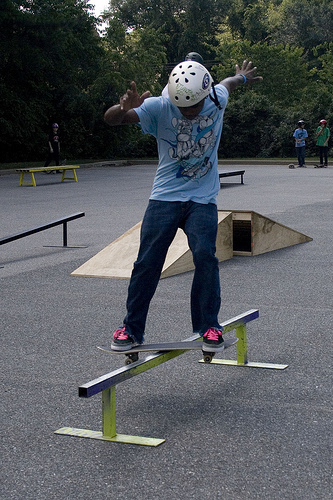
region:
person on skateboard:
[97, 71, 248, 363]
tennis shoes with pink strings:
[112, 321, 225, 352]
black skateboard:
[94, 335, 234, 362]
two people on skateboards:
[290, 114, 330, 169]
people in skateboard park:
[286, 117, 331, 169]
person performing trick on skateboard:
[95, 58, 267, 361]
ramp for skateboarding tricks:
[65, 197, 235, 276]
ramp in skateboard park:
[232, 205, 312, 253]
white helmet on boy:
[150, 58, 222, 112]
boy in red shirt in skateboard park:
[317, 116, 331, 162]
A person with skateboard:
[92, 80, 241, 358]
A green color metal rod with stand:
[69, 375, 169, 459]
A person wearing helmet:
[161, 54, 227, 109]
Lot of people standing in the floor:
[49, 119, 331, 152]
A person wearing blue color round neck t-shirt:
[155, 103, 231, 199]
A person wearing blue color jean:
[129, 205, 225, 322]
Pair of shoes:
[108, 329, 238, 347]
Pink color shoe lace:
[111, 326, 127, 338]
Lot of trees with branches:
[54, 3, 300, 51]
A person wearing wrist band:
[236, 70, 249, 86]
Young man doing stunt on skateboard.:
[92, 59, 273, 355]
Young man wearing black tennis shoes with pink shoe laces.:
[197, 326, 228, 353]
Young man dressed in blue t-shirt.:
[133, 82, 233, 204]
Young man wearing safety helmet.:
[167, 60, 215, 107]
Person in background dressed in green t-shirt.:
[314, 126, 332, 148]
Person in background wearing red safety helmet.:
[318, 119, 328, 126]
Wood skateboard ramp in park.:
[71, 207, 317, 280]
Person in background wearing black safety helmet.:
[295, 116, 307, 128]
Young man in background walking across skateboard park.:
[39, 117, 67, 173]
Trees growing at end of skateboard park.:
[5, 10, 106, 156]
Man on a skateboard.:
[102, 58, 262, 352]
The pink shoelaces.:
[203, 329, 221, 341]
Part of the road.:
[22, 289, 76, 357]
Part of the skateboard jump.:
[237, 208, 312, 255]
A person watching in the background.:
[43, 122, 63, 173]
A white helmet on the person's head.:
[166, 61, 220, 110]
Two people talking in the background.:
[292, 116, 329, 168]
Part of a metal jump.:
[55, 370, 172, 450]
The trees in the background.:
[239, 102, 283, 151]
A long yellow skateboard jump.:
[15, 165, 81, 184]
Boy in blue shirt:
[96, 47, 279, 302]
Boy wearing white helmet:
[91, 40, 270, 222]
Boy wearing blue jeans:
[98, 48, 277, 365]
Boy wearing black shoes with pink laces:
[89, 50, 268, 362]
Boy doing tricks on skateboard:
[84, 46, 291, 494]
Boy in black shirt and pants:
[33, 112, 82, 174]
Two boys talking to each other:
[277, 106, 332, 160]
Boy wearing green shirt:
[311, 112, 332, 167]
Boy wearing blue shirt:
[283, 111, 311, 170]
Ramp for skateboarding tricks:
[73, 187, 319, 295]